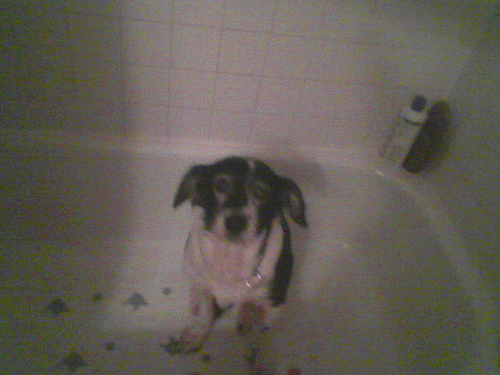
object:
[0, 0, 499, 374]
scene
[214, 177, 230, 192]
eye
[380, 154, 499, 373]
ledge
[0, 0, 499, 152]
wall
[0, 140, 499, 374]
bathtub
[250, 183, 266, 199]
eye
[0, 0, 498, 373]
bathroom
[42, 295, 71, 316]
decals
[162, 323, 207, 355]
paw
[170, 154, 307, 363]
dog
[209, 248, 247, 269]
fur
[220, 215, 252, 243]
snout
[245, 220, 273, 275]
collar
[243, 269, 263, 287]
loop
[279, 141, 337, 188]
shadow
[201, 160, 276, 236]
face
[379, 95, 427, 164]
bottle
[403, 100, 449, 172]
bottle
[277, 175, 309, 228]
ear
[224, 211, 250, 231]
nose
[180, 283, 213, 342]
leg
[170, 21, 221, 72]
tile